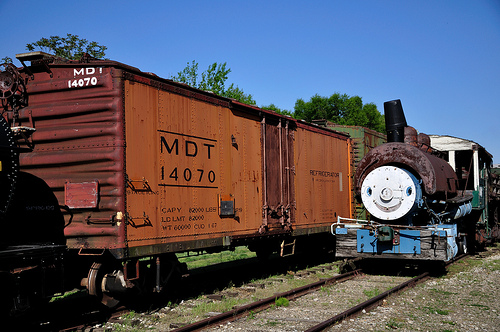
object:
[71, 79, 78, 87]
number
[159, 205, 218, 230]
writing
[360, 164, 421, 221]
face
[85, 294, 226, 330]
gravel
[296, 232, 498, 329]
track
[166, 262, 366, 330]
track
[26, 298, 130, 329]
track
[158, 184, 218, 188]
line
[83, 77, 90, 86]
number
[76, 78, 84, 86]
number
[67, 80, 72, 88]
number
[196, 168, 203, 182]
number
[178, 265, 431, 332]
rails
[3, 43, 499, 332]
railway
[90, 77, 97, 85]
number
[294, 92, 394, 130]
tree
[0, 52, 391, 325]
train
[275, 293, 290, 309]
grass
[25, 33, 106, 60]
trees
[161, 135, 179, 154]
letter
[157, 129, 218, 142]
line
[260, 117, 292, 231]
door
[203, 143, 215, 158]
letter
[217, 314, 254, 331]
pebbles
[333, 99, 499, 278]
train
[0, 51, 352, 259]
compartment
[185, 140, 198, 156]
letter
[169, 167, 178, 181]
number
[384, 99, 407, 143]
smokestack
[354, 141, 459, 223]
head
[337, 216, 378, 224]
metal bar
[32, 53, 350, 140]
top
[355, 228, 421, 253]
blue paint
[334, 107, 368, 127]
leaves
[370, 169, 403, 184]
paint